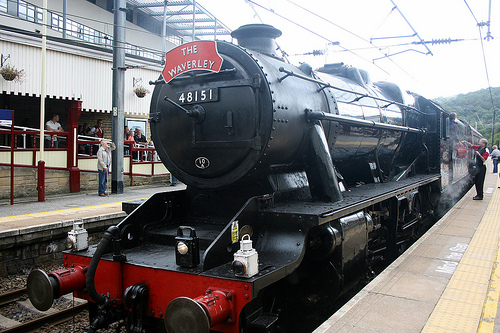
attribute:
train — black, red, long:
[69, 75, 497, 313]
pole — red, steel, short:
[0, 90, 26, 203]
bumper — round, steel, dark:
[37, 264, 192, 330]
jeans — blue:
[92, 166, 116, 195]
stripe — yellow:
[2, 186, 144, 237]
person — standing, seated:
[466, 141, 490, 208]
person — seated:
[77, 120, 102, 153]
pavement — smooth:
[344, 211, 497, 332]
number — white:
[168, 75, 222, 114]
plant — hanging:
[1, 64, 30, 83]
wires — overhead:
[253, 5, 497, 72]